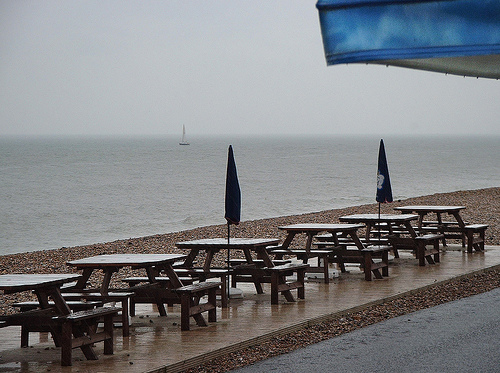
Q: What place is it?
A: It is a beach.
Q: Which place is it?
A: It is a beach.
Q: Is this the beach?
A: Yes, it is the beach.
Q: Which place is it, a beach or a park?
A: It is a beach.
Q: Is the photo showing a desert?
A: No, the picture is showing a beach.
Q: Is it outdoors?
A: Yes, it is outdoors.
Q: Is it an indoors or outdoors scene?
A: It is outdoors.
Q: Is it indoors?
A: No, it is outdoors.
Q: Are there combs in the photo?
A: No, there are no combs.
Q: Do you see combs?
A: No, there are no combs.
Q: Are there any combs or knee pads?
A: No, there are no combs or knee pads.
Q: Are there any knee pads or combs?
A: No, there are no combs or knee pads.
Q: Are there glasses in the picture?
A: No, there are no glasses.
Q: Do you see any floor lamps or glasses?
A: No, there are no glasses or floor lamps.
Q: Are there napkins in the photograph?
A: No, there are no napkins.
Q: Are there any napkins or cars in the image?
A: No, there are no napkins or cars.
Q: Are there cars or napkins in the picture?
A: No, there are no napkins or cars.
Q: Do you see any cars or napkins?
A: No, there are no napkins or cars.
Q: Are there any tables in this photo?
A: Yes, there is a table.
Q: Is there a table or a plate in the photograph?
A: Yes, there is a table.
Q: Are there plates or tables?
A: Yes, there is a table.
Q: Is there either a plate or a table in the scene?
A: Yes, there is a table.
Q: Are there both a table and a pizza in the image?
A: No, there is a table but no pizzas.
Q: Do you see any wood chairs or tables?
A: Yes, there is a wood table.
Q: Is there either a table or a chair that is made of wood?
A: Yes, the table is made of wood.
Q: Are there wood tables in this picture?
A: Yes, there is a wood table.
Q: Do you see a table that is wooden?
A: Yes, there is a table that is wooden.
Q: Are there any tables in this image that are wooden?
A: Yes, there is a table that is wooden.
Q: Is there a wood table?
A: Yes, there is a table that is made of wood.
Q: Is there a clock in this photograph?
A: No, there are no clocks.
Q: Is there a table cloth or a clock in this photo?
A: No, there are no clocks or tablecloths.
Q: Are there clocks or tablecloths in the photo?
A: No, there are no clocks or tablecloths.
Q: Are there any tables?
A: Yes, there is a table.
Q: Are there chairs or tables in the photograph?
A: Yes, there is a table.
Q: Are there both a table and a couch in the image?
A: No, there is a table but no couches.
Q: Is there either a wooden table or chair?
A: Yes, there is a wood table.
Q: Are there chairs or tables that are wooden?
A: Yes, the table is wooden.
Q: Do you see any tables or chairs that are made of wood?
A: Yes, the table is made of wood.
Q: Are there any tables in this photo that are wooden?
A: Yes, there is a wood table.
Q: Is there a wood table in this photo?
A: Yes, there is a wood table.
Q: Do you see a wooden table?
A: Yes, there is a wood table.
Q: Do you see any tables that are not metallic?
A: Yes, there is a wooden table.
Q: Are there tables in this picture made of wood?
A: Yes, there is a table that is made of wood.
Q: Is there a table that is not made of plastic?
A: Yes, there is a table that is made of wood.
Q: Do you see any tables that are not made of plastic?
A: Yes, there is a table that is made of wood.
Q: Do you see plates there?
A: No, there are no plates.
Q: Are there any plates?
A: No, there are no plates.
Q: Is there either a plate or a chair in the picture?
A: No, there are no plates or chairs.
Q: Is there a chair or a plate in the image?
A: No, there are no plates or chairs.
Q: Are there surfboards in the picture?
A: No, there are no surfboards.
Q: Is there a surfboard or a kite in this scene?
A: No, there are no surfboards or kites.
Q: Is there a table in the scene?
A: Yes, there is a table.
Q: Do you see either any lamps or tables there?
A: Yes, there is a table.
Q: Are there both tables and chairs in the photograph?
A: No, there is a table but no chairs.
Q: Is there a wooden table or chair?
A: Yes, there is a wood table.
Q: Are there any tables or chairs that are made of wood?
A: Yes, the table is made of wood.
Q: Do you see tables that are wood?
A: Yes, there is a wood table.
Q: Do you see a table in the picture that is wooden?
A: Yes, there is a table that is wooden.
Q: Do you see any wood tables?
A: Yes, there is a table that is made of wood.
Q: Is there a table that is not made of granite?
A: Yes, there is a table that is made of wood.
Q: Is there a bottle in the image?
A: No, there are no bottles.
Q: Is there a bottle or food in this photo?
A: No, there are no bottles or food.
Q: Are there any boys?
A: No, there are no boys.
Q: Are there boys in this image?
A: No, there are no boys.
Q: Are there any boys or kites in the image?
A: No, there are no boys or kites.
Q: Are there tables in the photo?
A: Yes, there is a table.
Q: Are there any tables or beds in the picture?
A: Yes, there is a table.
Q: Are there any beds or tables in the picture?
A: Yes, there is a table.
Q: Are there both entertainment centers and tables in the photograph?
A: No, there is a table but no entertainment centers.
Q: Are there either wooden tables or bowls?
A: Yes, there is a wood table.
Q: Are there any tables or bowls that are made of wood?
A: Yes, the table is made of wood.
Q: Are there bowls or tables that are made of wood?
A: Yes, the table is made of wood.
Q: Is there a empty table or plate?
A: Yes, there is an empty table.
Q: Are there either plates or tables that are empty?
A: Yes, the table is empty.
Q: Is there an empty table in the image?
A: Yes, there is an empty table.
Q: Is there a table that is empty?
A: Yes, there is an empty table.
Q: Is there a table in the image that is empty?
A: Yes, there is a table that is empty.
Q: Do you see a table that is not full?
A: Yes, there is a empty table.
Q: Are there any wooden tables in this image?
A: Yes, there is a wood table.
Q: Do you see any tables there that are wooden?
A: Yes, there is a table that is wooden.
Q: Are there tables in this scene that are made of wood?
A: Yes, there is a table that is made of wood.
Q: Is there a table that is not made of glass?
A: Yes, there is a table that is made of wood.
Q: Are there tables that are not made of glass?
A: Yes, there is a table that is made of wood.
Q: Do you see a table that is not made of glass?
A: Yes, there is a table that is made of wood.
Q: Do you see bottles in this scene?
A: No, there are no bottles.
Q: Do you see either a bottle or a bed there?
A: No, there are no bottles or beds.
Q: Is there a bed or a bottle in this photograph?
A: No, there are no bottles or beds.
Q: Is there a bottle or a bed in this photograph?
A: No, there are no bottles or beds.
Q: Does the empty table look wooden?
A: Yes, the table is wooden.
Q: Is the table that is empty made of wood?
A: Yes, the table is made of wood.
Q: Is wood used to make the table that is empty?
A: Yes, the table is made of wood.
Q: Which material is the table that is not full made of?
A: The table is made of wood.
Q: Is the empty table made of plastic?
A: No, the table is made of wood.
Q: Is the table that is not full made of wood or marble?
A: The table is made of wood.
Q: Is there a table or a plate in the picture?
A: Yes, there is a table.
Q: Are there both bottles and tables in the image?
A: No, there is a table but no bottles.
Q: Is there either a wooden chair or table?
A: Yes, there is a wood table.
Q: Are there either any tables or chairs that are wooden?
A: Yes, the table is wooden.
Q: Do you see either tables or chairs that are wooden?
A: Yes, the table is wooden.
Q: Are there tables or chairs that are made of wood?
A: Yes, the table is made of wood.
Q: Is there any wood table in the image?
A: Yes, there is a wood table.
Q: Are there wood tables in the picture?
A: Yes, there is a wood table.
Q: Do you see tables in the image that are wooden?
A: Yes, there is a table that is wooden.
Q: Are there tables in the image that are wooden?
A: Yes, there is a table that is wooden.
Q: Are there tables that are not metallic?
A: Yes, there is a wooden table.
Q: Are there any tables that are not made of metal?
A: Yes, there is a table that is made of wood.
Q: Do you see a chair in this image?
A: No, there are no chairs.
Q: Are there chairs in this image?
A: No, there are no chairs.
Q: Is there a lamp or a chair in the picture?
A: No, there are no chairs or lamps.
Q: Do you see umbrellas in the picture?
A: Yes, there is an umbrella.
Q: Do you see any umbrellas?
A: Yes, there is an umbrella.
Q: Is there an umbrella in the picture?
A: Yes, there is an umbrella.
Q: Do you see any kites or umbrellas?
A: Yes, there is an umbrella.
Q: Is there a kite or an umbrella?
A: Yes, there is an umbrella.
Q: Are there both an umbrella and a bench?
A: Yes, there are both an umbrella and a bench.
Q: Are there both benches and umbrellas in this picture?
A: Yes, there are both an umbrella and a bench.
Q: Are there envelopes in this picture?
A: No, there are no envelopes.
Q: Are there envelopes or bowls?
A: No, there are no envelopes or bowls.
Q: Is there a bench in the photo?
A: Yes, there is a bench.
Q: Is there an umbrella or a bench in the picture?
A: Yes, there is a bench.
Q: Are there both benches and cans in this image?
A: No, there is a bench but no cans.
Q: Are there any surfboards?
A: No, there are no surfboards.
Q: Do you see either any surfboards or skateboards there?
A: No, there are no surfboards or skateboards.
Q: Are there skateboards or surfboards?
A: No, there are no surfboards or skateboards.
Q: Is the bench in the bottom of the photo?
A: Yes, the bench is in the bottom of the image.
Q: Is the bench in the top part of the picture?
A: No, the bench is in the bottom of the image.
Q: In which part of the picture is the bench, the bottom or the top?
A: The bench is in the bottom of the image.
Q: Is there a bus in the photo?
A: No, there are no buses.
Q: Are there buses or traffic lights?
A: No, there are no buses or traffic lights.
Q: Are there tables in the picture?
A: Yes, there is a table.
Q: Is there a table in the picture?
A: Yes, there is a table.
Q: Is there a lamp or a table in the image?
A: Yes, there is a table.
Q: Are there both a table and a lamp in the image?
A: No, there is a table but no lamps.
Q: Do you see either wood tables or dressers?
A: Yes, there is a wood table.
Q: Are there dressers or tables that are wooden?
A: Yes, the table is wooden.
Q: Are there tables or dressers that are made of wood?
A: Yes, the table is made of wood.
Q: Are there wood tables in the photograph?
A: Yes, there is a wood table.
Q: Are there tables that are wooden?
A: Yes, there is a table that is wooden.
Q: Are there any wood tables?
A: Yes, there is a table that is made of wood.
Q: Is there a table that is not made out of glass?
A: Yes, there is a table that is made of wood.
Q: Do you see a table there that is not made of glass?
A: Yes, there is a table that is made of wood.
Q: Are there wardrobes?
A: No, there are no wardrobes.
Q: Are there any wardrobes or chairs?
A: No, there are no wardrobes or chairs.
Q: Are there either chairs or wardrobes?
A: No, there are no wardrobes or chairs.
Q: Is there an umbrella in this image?
A: Yes, there is an umbrella.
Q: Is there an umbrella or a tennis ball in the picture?
A: Yes, there is an umbrella.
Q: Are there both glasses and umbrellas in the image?
A: No, there is an umbrella but no glasses.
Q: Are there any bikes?
A: No, there are no bikes.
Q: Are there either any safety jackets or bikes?
A: No, there are no bikes or safety jackets.